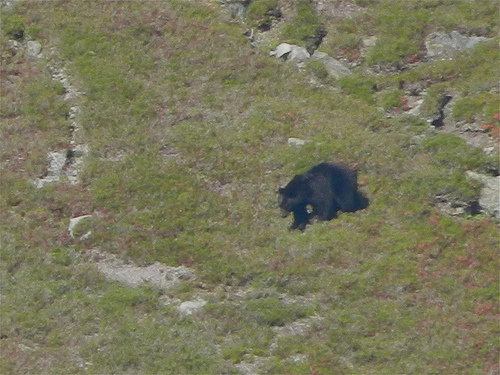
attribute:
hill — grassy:
[0, 2, 481, 374]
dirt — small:
[86, 245, 196, 295]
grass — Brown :
[38, 180, 104, 222]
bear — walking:
[251, 152, 376, 242]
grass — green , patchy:
[5, 1, 498, 365]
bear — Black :
[275, 161, 370, 220]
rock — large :
[265, 36, 333, 84]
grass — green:
[6, 14, 319, 159]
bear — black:
[271, 167, 360, 229]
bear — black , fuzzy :
[265, 150, 366, 229]